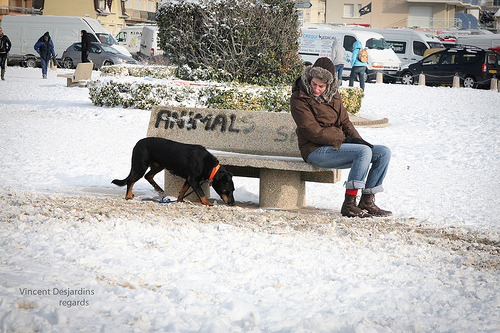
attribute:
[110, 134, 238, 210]
dog — sniffing, walking, black, sniffing ground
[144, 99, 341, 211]
bench — concrete, cement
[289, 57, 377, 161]
jacket — brown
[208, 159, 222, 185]
collar — red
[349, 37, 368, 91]
woman — walking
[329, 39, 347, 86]
woman — walking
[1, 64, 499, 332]
ground — snow-covered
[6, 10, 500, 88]
vehicles — parked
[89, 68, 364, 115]
bushes — snow-covered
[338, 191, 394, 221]
boots — brown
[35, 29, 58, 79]
man — walking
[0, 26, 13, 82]
man — walking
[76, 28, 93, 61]
man — walking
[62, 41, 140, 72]
car — parked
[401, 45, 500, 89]
car — parked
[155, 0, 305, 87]
bush — snow-covered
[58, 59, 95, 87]
bench — empty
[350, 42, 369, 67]
coat — blue